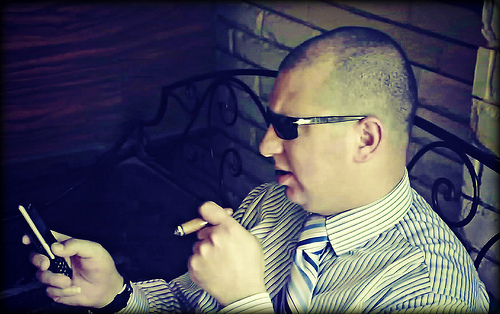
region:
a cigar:
[167, 217, 198, 239]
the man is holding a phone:
[11, 195, 84, 246]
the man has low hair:
[338, 48, 399, 96]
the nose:
[255, 140, 281, 157]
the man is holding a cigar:
[168, 207, 238, 248]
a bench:
[131, 114, 219, 204]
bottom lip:
[270, 172, 292, 185]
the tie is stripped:
[298, 224, 323, 271]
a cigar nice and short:
[169, 203, 235, 237]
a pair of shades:
[259, 99, 367, 144]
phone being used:
[11, 188, 77, 280]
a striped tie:
[276, 212, 328, 312]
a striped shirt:
[121, 173, 492, 311]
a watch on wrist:
[93, 274, 138, 312]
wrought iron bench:
[0, 62, 499, 310]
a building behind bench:
[215, 0, 497, 299]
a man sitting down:
[14, 22, 491, 313]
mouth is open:
[269, 162, 293, 189]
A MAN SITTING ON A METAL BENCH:
[8, 22, 497, 307]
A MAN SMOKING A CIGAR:
[11, 22, 491, 306]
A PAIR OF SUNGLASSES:
[261, 99, 376, 142]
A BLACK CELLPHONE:
[13, 194, 78, 281]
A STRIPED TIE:
[281, 210, 333, 311]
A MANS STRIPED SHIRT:
[116, 162, 497, 309]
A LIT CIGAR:
[166, 211, 241, 238]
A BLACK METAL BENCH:
[82, 59, 492, 305]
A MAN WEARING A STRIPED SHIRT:
[20, 20, 493, 312]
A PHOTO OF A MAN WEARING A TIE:
[16, 20, 490, 308]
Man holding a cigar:
[8, 12, 494, 309]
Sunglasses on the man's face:
[262, 98, 365, 146]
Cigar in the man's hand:
[169, 200, 239, 238]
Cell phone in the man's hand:
[14, 199, 85, 286]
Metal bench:
[77, 80, 490, 295]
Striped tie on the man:
[280, 210, 325, 306]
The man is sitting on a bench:
[26, 99, 490, 301]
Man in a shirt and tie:
[107, 29, 488, 308]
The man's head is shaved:
[240, 28, 420, 165]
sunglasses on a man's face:
[262, 104, 365, 139]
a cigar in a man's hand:
[175, 207, 234, 237]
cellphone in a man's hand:
[16, 196, 123, 307]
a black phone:
[15, 199, 74, 284]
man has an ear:
[355, 114, 382, 166]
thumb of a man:
[50, 237, 97, 259]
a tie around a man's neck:
[275, 213, 332, 313]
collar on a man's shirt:
[323, 168, 413, 253]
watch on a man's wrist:
[92, 277, 134, 312]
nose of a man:
[260, 124, 285, 156]